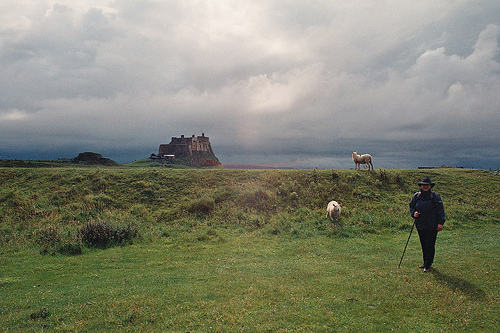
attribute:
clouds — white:
[62, 34, 294, 119]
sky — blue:
[112, 21, 442, 155]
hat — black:
[407, 174, 436, 188]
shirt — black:
[407, 190, 444, 222]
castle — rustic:
[149, 129, 214, 167]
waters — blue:
[401, 126, 477, 163]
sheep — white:
[330, 146, 408, 168]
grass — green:
[1, 161, 498, 331]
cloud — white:
[6, 1, 336, 105]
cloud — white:
[263, 21, 499, 154]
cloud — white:
[0, 70, 303, 143]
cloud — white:
[228, 0, 485, 69]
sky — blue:
[0, 4, 496, 164]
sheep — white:
[325, 185, 348, 226]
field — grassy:
[1, 165, 498, 332]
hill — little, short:
[10, 171, 494, 241]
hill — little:
[1, 163, 479, 248]